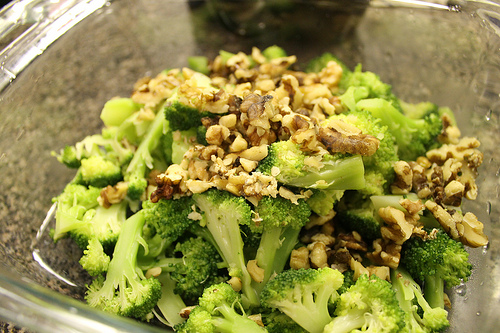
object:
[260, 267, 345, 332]
broccoli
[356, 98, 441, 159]
veggie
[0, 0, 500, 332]
bowl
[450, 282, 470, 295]
water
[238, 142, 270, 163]
nut